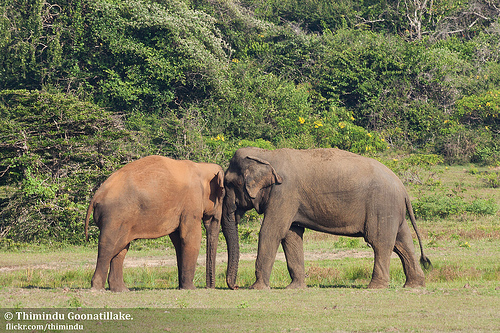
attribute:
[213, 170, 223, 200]
ear — large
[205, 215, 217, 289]
trunk — long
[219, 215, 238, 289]
trunk — long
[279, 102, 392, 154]
flowers — yellow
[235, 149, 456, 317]
elephant — big, gray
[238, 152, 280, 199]
ear — large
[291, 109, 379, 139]
flowers — yellow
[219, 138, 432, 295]
elephant — older, dark, brown, larger, darker, gray, big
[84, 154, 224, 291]
elephant — smaller, red-tinted, young, brown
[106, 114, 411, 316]
elephant — brown, gray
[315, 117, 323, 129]
flower — yellow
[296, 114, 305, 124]
flower — yellow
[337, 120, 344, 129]
flower — yellow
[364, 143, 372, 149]
flower — yellow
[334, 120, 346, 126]
flower — yellow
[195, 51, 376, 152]
tree — yellow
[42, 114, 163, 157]
stick — brown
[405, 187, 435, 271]
tail — long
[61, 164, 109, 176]
stick — brown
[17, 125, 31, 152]
stick — brown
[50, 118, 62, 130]
stick — brown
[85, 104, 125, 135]
stick — brown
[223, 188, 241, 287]
trunk — elephants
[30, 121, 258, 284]
elephant — playing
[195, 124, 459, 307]
elephant — playing